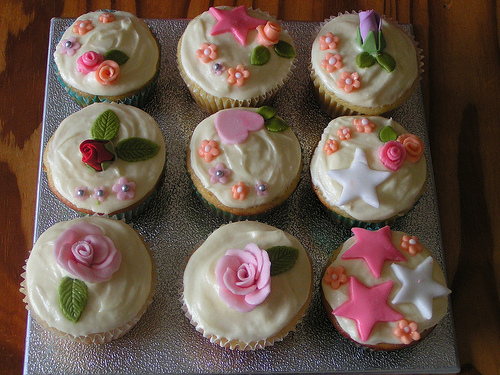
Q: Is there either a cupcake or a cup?
A: Yes, there is a cupcake.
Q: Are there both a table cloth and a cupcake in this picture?
A: No, there is a cupcake but no tablecloths.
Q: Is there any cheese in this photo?
A: No, there is no cheese.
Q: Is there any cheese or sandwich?
A: No, there are no cheese or sandwiches.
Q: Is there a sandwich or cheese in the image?
A: No, there are no cheese or sandwiches.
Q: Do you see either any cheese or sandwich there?
A: No, there are no cheese or sandwiches.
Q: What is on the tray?
A: The cupcake is on the tray.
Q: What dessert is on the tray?
A: The dessert is a cupcake.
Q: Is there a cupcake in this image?
A: Yes, there is a cupcake.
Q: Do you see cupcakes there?
A: Yes, there is a cupcake.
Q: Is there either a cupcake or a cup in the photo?
A: Yes, there is a cupcake.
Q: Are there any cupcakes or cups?
A: Yes, there is a cupcake.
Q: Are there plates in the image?
A: No, there are no plates.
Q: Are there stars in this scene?
A: Yes, there is a star.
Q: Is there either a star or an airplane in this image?
A: Yes, there is a star.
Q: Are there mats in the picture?
A: No, there are no mats.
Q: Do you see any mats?
A: No, there are no mats.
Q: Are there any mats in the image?
A: No, there are no mats.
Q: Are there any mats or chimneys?
A: No, there are no mats or chimneys.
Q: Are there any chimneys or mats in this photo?
A: No, there are no mats or chimneys.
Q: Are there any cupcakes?
A: Yes, there is a cupcake.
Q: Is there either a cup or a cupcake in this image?
A: Yes, there is a cupcake.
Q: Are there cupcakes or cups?
A: Yes, there is a cupcake.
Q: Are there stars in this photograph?
A: Yes, there is a star.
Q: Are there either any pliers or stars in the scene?
A: Yes, there is a star.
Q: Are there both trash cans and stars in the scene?
A: No, there is a star but no trash cans.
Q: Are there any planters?
A: No, there are no planters.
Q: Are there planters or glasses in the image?
A: No, there are no planters or glasses.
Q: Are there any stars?
A: Yes, there is a star.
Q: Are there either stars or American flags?
A: Yes, there is a star.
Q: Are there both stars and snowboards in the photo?
A: No, there is a star but no snowboards.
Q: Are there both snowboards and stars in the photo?
A: No, there is a star but no snowboards.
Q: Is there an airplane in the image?
A: No, there are no airplanes.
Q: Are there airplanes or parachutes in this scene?
A: No, there are no airplanes or parachutes.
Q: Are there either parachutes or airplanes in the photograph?
A: No, there are no airplanes or parachutes.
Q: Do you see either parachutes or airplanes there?
A: No, there are no airplanes or parachutes.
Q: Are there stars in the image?
A: Yes, there is a star.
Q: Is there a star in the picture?
A: Yes, there is a star.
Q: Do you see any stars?
A: Yes, there is a star.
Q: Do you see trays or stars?
A: Yes, there is a star.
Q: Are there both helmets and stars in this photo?
A: No, there is a star but no helmets.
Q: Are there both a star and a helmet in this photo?
A: No, there is a star but no helmets.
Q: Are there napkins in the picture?
A: No, there are no napkins.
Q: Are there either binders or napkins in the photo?
A: No, there are no napkins or binders.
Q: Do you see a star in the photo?
A: Yes, there is a star.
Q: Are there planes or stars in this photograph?
A: Yes, there is a star.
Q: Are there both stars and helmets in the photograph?
A: No, there is a star but no helmets.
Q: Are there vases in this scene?
A: No, there are no vases.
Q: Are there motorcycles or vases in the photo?
A: No, there are no vases or motorcycles.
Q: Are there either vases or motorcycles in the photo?
A: No, there are no vases or motorcycles.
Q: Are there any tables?
A: Yes, there is a table.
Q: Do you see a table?
A: Yes, there is a table.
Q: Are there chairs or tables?
A: Yes, there is a table.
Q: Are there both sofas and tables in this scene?
A: No, there is a table but no sofas.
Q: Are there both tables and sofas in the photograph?
A: No, there is a table but no sofas.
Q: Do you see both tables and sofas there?
A: No, there is a table but no sofas.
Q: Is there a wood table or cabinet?
A: Yes, there is a wood table.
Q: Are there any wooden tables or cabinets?
A: Yes, there is a wood table.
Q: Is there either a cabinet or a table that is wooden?
A: Yes, the table is wooden.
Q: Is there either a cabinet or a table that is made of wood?
A: Yes, the table is made of wood.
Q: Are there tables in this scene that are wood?
A: Yes, there is a wood table.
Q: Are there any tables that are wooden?
A: Yes, there is a table that is wooden.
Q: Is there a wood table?
A: Yes, there is a table that is made of wood.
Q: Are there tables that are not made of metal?
A: Yes, there is a table that is made of wood.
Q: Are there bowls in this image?
A: No, there are no bowls.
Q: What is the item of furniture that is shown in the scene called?
A: The piece of furniture is a table.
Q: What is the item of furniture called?
A: The piece of furniture is a table.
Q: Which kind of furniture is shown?
A: The furniture is a table.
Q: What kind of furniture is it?
A: The piece of furniture is a table.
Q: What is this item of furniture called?
A: This is a table.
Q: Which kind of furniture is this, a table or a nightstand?
A: This is a table.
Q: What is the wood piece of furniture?
A: The piece of furniture is a table.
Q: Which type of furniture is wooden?
A: The furniture is a table.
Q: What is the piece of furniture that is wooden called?
A: The piece of furniture is a table.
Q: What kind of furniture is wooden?
A: The furniture is a table.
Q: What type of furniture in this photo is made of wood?
A: The furniture is a table.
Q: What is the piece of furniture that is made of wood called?
A: The piece of furniture is a table.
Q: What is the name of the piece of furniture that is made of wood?
A: The piece of furniture is a table.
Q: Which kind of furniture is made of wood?
A: The furniture is a table.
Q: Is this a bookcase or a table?
A: This is a table.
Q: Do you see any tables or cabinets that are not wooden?
A: No, there is a table but it is wooden.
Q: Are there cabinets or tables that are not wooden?
A: No, there is a table but it is wooden.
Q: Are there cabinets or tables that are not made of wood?
A: No, there is a table but it is made of wood.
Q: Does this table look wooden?
A: Yes, the table is wooden.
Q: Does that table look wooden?
A: Yes, the table is wooden.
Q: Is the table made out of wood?
A: Yes, the table is made of wood.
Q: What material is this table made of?
A: The table is made of wood.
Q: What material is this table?
A: The table is made of wood.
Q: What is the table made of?
A: The table is made of wood.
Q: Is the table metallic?
A: No, the table is wooden.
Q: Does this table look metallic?
A: No, the table is wooden.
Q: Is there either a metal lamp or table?
A: No, there is a table but it is wooden.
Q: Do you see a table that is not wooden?
A: No, there is a table but it is wooden.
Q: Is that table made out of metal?
A: No, the table is made of wood.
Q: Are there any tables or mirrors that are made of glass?
A: No, there is a table but it is made of wood.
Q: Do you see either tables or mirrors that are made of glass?
A: No, there is a table but it is made of wood.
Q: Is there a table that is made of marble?
A: No, there is a table but it is made of wood.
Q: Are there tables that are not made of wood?
A: No, there is a table but it is made of wood.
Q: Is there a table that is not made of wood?
A: No, there is a table but it is made of wood.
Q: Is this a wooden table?
A: Yes, this is a wooden table.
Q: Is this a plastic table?
A: No, this is a wooden table.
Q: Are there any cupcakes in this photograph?
A: Yes, there is a cupcake.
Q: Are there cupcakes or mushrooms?
A: Yes, there is a cupcake.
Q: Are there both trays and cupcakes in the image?
A: Yes, there are both a cupcake and a tray.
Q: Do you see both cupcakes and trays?
A: Yes, there are both a cupcake and a tray.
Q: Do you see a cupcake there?
A: Yes, there is a cupcake.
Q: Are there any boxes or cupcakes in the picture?
A: Yes, there is a cupcake.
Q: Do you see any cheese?
A: No, there is no cheese.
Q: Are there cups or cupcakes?
A: Yes, there is a cupcake.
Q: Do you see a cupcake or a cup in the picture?
A: Yes, there is a cupcake.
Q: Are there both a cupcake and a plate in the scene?
A: No, there is a cupcake but no plates.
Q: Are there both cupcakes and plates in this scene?
A: No, there is a cupcake but no plates.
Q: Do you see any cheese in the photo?
A: No, there is no cheese.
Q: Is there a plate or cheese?
A: No, there are no cheese or plates.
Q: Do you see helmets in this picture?
A: No, there are no helmets.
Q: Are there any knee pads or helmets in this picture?
A: No, there are no helmets or knee pads.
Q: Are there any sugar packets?
A: No, there are no sugar packets.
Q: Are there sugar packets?
A: No, there are no sugar packets.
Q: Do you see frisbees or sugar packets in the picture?
A: No, there are no sugar packets or frisbees.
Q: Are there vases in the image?
A: No, there are no vases.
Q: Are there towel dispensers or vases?
A: No, there are no vases or towel dispensers.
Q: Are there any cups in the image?
A: No, there are no cups.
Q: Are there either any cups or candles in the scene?
A: No, there are no cups or candles.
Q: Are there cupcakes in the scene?
A: Yes, there is a cupcake.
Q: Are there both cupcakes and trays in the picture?
A: Yes, there are both a cupcake and a tray.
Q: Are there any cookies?
A: No, there are no cookies.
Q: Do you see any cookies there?
A: No, there are no cookies.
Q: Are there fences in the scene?
A: No, there are no fences.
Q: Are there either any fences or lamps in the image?
A: No, there are no fences or lamps.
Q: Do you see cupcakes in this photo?
A: Yes, there is a cupcake.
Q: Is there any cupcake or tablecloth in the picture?
A: Yes, there is a cupcake.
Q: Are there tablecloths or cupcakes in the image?
A: Yes, there is a cupcake.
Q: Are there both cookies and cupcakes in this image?
A: No, there is a cupcake but no cookies.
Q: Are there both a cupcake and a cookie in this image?
A: No, there is a cupcake but no cookies.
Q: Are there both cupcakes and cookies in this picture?
A: No, there is a cupcake but no cookies.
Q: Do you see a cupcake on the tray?
A: Yes, there is a cupcake on the tray.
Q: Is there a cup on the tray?
A: No, there is a cupcake on the tray.